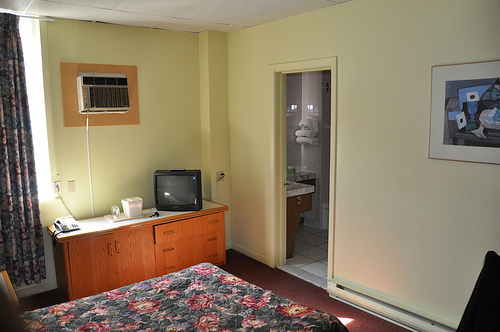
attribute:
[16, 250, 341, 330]
quilt — flower patterned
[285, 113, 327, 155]
towels — white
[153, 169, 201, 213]
tv — black, old style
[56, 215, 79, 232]
telephone — white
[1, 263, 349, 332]
design — floral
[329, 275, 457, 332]
heater — white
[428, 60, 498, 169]
artwork — hanging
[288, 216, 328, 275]
floor — white, tile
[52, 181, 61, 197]
outlet — white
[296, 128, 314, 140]
towel — white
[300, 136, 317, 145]
towel — white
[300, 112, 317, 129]
towel — white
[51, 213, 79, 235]
telephone — white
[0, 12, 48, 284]
curtain — floral design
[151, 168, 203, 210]
television — small, black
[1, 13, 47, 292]
flower curtain — floral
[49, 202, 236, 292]
dresser — light, wooden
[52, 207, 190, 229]
top — white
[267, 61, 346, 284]
bathroom — tiled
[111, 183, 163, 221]
container — white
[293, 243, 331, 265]
tile — white 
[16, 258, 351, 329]
sheet — bed, printed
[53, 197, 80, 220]
cord — white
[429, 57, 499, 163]
art — framed